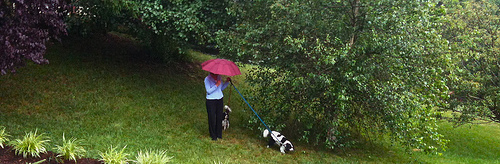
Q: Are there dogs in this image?
A: Yes, there is a dog.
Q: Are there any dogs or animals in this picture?
A: Yes, there is a dog.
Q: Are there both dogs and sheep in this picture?
A: No, there is a dog but no sheep.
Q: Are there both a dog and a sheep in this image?
A: No, there is a dog but no sheep.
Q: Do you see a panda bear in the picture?
A: No, there are no panda bears.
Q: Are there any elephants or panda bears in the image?
A: No, there are no panda bears or elephants.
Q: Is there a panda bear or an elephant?
A: No, there are no panda bears or elephants.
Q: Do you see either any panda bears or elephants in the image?
A: No, there are no panda bears or elephants.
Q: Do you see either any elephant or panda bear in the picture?
A: No, there are no panda bears or elephants.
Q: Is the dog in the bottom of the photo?
A: Yes, the dog is in the bottom of the image.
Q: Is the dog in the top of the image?
A: No, the dog is in the bottom of the image.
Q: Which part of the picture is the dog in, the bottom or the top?
A: The dog is in the bottom of the image.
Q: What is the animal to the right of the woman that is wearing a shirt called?
A: The animal is a dog.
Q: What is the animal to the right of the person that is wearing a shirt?
A: The animal is a dog.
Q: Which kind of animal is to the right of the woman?
A: The animal is a dog.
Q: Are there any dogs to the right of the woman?
A: Yes, there is a dog to the right of the woman.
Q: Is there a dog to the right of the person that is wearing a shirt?
A: Yes, there is a dog to the right of the woman.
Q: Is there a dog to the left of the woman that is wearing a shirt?
A: No, the dog is to the right of the woman.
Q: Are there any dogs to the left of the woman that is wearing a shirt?
A: No, the dog is to the right of the woman.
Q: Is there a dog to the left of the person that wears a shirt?
A: No, the dog is to the right of the woman.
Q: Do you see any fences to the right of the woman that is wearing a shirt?
A: No, there is a dog to the right of the woman.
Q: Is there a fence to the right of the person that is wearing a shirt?
A: No, there is a dog to the right of the woman.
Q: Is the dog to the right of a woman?
A: Yes, the dog is to the right of a woman.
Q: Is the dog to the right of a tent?
A: No, the dog is to the right of a woman.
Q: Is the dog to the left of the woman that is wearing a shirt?
A: No, the dog is to the right of the woman.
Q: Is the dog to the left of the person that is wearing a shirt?
A: No, the dog is to the right of the woman.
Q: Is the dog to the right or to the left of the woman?
A: The dog is to the right of the woman.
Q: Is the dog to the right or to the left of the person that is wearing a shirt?
A: The dog is to the right of the woman.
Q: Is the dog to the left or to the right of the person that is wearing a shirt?
A: The dog is to the right of the woman.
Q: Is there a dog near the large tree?
A: Yes, there is a dog near the tree.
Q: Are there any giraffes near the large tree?
A: No, there is a dog near the tree.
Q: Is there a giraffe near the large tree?
A: No, there is a dog near the tree.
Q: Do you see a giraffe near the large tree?
A: No, there is a dog near the tree.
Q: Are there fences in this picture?
A: No, there are no fences.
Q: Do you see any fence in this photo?
A: No, there are no fences.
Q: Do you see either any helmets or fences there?
A: No, there are no fences or helmets.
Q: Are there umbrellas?
A: Yes, there is an umbrella.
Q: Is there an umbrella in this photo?
A: Yes, there is an umbrella.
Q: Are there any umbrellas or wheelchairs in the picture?
A: Yes, there is an umbrella.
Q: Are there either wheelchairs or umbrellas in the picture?
A: Yes, there is an umbrella.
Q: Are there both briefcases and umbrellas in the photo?
A: No, there is an umbrella but no briefcases.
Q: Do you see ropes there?
A: No, there are no ropes.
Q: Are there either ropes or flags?
A: No, there are no ropes or flags.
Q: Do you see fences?
A: No, there are no fences.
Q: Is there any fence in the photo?
A: No, there are no fences.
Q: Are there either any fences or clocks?
A: No, there are no fences or clocks.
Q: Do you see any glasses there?
A: No, there are no glasses.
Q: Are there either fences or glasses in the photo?
A: No, there are no glasses or fences.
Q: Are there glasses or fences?
A: No, there are no glasses or fences.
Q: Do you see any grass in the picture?
A: Yes, there is grass.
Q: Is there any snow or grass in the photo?
A: Yes, there is grass.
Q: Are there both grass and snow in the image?
A: No, there is grass but no snow.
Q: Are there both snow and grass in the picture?
A: No, there is grass but no snow.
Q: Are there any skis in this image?
A: No, there are no skis.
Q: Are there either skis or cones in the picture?
A: No, there are no skis or cones.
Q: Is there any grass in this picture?
A: Yes, there is grass.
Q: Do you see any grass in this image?
A: Yes, there is grass.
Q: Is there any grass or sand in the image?
A: Yes, there is grass.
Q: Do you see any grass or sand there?
A: Yes, there is grass.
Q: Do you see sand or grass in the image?
A: Yes, there is grass.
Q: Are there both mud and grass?
A: No, there is grass but no mud.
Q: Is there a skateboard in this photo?
A: No, there are no skateboards.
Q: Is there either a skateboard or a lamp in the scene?
A: No, there are no skateboards or lamps.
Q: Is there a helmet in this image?
A: No, there are no helmets.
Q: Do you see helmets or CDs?
A: No, there are no helmets or cds.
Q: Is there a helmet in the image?
A: No, there are no helmets.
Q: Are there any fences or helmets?
A: No, there are no helmets or fences.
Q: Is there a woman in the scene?
A: Yes, there is a woman.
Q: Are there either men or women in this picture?
A: Yes, there is a woman.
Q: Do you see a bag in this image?
A: No, there are no bags.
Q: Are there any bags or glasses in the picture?
A: No, there are no bags or glasses.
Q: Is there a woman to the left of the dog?
A: Yes, there is a woman to the left of the dog.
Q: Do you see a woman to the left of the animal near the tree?
A: Yes, there is a woman to the left of the dog.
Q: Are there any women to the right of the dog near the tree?
A: No, the woman is to the left of the dog.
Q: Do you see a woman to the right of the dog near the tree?
A: No, the woman is to the left of the dog.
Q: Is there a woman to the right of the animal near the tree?
A: No, the woman is to the left of the dog.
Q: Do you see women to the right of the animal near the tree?
A: No, the woman is to the left of the dog.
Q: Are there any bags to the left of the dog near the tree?
A: No, there is a woman to the left of the dog.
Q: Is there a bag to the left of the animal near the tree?
A: No, there is a woman to the left of the dog.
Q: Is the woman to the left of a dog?
A: Yes, the woman is to the left of a dog.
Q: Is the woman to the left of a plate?
A: No, the woman is to the left of a dog.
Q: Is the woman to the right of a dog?
A: No, the woman is to the left of a dog.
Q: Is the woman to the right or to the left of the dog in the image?
A: The woman is to the left of the dog.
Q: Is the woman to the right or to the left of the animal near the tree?
A: The woman is to the left of the dog.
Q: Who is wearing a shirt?
A: The woman is wearing a shirt.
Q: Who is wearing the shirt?
A: The woman is wearing a shirt.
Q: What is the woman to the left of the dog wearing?
A: The woman is wearing a shirt.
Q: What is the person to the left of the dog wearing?
A: The woman is wearing a shirt.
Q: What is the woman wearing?
A: The woman is wearing a shirt.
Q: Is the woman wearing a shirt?
A: Yes, the woman is wearing a shirt.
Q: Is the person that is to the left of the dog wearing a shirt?
A: Yes, the woman is wearing a shirt.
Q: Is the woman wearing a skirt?
A: No, the woman is wearing a shirt.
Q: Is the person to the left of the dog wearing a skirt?
A: No, the woman is wearing a shirt.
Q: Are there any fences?
A: No, there are no fences.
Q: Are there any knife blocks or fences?
A: No, there are no fences or knife blocks.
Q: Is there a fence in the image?
A: No, there are no fences.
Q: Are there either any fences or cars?
A: No, there are no fences or cars.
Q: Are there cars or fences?
A: No, there are no fences or cars.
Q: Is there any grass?
A: Yes, there is grass.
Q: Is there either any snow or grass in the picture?
A: Yes, there is grass.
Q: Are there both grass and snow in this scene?
A: No, there is grass but no snow.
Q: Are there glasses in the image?
A: No, there are no glasses.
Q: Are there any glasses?
A: No, there are no glasses.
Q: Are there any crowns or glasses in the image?
A: No, there are no glasses or crowns.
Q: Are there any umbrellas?
A: Yes, there is an umbrella.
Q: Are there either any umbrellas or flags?
A: Yes, there is an umbrella.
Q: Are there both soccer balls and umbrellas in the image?
A: No, there is an umbrella but no soccer balls.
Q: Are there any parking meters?
A: No, there are no parking meters.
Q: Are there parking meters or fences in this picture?
A: No, there are no parking meters or fences.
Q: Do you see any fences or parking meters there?
A: No, there are no parking meters or fences.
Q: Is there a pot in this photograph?
A: No, there are no pots.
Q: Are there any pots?
A: No, there are no pots.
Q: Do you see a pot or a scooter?
A: No, there are no pots or scooters.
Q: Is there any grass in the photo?
A: Yes, there is grass.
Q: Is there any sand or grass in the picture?
A: Yes, there is grass.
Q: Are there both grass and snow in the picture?
A: No, there is grass but no snow.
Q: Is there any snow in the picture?
A: No, there is no snow.